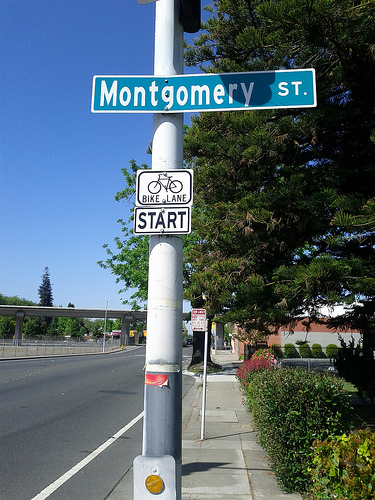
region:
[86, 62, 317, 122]
blue rectangular street sign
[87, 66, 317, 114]
street sign on metal pole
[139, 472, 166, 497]
light reflector on metal pole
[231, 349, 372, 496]
row of shrubbery along sidewalk edge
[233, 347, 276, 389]
red shrub at end of row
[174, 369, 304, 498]
concrete sidewalk near shrubs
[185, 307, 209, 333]
red and white parking sign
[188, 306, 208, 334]
red and white rectangular sign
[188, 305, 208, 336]
red and white sign on metal pole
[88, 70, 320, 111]
Green street sign with with letters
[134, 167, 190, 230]
White sign with black letters and emblem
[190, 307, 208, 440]
White and red sign on pole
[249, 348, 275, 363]
Pink flowers on bush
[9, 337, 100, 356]
Silver chain link fence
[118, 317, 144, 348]
Cement columns under overpass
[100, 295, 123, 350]
Tall silver street light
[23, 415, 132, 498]
White line painted on street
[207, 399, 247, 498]
Cracks in cement sidewalk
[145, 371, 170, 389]
Red tape on pole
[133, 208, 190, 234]
start on the sign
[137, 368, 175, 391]
red sticker on the pole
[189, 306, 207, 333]
red and white sign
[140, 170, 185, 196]
bike on the sign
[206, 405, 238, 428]
square on the sidewalk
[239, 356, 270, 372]
red flowering bush beside the sidewalk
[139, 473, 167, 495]
yellow light on the pole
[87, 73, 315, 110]
green and white sign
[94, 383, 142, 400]
shadow on the road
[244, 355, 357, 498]
a row of bushes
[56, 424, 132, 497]
a white line painted on a road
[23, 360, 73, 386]
yellow lines painted on a road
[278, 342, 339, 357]
a row of hedge bushes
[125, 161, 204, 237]
a black and white sign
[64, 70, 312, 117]
a blue and white street sign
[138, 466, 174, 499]
a yellow reflector on a pole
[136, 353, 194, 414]
red sticker on metal light pole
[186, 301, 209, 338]
red and white directional sign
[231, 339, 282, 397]
green brush with red flowers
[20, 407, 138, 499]
white line painted on roadway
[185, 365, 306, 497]
cement sidewalk in city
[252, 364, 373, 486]
green leafy shrubs along city sidewalk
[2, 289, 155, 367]
bridge over roadway at a distance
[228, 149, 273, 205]
green leaves on the tree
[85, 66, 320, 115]
green and white street sign on metal pole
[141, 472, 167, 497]
yellow circular dot on side of metal pole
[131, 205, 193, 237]
black and white sign on metal pole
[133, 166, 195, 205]
black and white sign with bicycle on it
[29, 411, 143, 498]
white line painted on street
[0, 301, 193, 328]
stone bridge over street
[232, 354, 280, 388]
red bush on side of sidewalk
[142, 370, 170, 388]
piece of red tape on metal pole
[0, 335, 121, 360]
metal fence on side of street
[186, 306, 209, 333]
red and white traffic sign on sidewalk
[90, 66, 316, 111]
the street sign is green and white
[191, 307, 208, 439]
the sign on the pole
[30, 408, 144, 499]
the line is white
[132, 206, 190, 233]
the sign say's START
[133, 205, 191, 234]
the sign is black and white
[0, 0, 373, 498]
the blue sky above the roads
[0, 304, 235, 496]
the overpass above the road